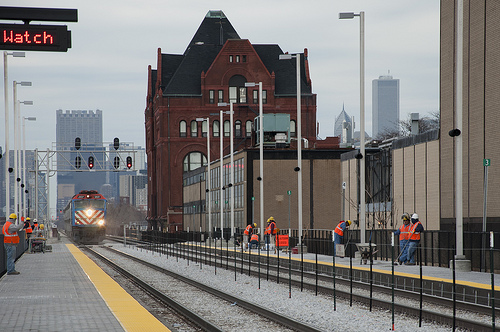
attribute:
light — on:
[84, 207, 94, 216]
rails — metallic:
[90, 221, 302, 324]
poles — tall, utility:
[196, 2, 479, 257]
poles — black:
[125, 226, 499, 330]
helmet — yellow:
[6, 214, 23, 224]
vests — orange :
[242, 221, 421, 241]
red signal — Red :
[87, 162, 95, 169]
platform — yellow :
[27, 250, 157, 328]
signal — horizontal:
[82, 153, 98, 172]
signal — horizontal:
[120, 152, 135, 169]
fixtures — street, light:
[336, 10, 360, 20]